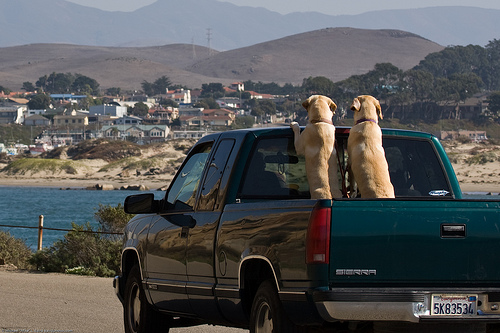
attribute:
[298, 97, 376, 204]
dogs — blonde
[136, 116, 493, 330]
truck — green, dark green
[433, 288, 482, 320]
tag — white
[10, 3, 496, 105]
mountains — in background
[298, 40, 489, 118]
trees — green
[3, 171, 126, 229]
water — blue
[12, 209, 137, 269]
bushes — green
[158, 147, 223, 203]
window — glass, open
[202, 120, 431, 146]
roof — blue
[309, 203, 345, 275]
tail light — red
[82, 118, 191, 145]
house — large